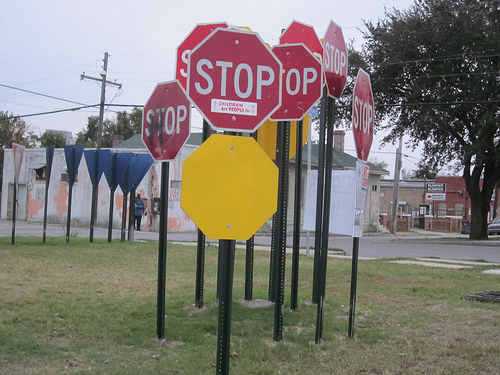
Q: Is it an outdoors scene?
A: Yes, it is outdoors.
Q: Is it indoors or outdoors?
A: It is outdoors.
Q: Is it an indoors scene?
A: No, it is outdoors.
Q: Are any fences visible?
A: No, there are no fences.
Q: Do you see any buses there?
A: No, there are no buses.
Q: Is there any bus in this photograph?
A: No, there are no buses.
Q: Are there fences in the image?
A: No, there are no fences.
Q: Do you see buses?
A: No, there are no buses.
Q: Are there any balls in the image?
A: No, there are no balls.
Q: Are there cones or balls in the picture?
A: No, there are no balls or cones.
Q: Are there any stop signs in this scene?
A: Yes, there is a stop sign.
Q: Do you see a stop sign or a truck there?
A: Yes, there is a stop sign.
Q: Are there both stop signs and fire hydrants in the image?
A: No, there is a stop sign but no fire hydrants.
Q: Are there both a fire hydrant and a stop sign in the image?
A: No, there is a stop sign but no fire hydrants.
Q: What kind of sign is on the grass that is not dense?
A: The sign is a stop sign.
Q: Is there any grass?
A: Yes, there is grass.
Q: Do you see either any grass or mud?
A: Yes, there is grass.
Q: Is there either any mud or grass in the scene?
A: Yes, there is grass.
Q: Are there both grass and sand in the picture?
A: No, there is grass but no sand.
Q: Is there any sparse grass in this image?
A: Yes, there is sparse grass.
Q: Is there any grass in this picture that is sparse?
A: Yes, there is sparse grass.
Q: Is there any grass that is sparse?
A: Yes, there is grass that is sparse.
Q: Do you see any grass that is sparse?
A: Yes, there is grass that is sparse.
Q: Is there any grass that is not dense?
A: Yes, there is sparse grass.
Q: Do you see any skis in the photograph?
A: No, there are no skis.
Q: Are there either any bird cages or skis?
A: No, there are no skis or bird cages.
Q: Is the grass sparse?
A: Yes, the grass is sparse.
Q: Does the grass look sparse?
A: Yes, the grass is sparse.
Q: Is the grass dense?
A: No, the grass is sparse.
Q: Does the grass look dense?
A: No, the grass is sparse.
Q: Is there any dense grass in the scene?
A: No, there is grass but it is sparse.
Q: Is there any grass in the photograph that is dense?
A: No, there is grass but it is sparse.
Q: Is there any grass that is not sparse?
A: No, there is grass but it is sparse.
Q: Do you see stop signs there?
A: Yes, there is a stop sign.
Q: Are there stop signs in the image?
A: Yes, there is a stop sign.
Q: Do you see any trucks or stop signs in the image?
A: Yes, there is a stop sign.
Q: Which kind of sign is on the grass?
A: The sign is a stop sign.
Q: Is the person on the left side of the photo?
A: Yes, the person is on the left of the image.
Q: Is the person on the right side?
A: No, the person is on the left of the image.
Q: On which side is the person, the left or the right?
A: The person is on the left of the image.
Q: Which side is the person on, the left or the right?
A: The person is on the left of the image.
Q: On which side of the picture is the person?
A: The person is on the left of the image.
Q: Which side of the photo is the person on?
A: The person is on the left of the image.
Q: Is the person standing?
A: Yes, the person is standing.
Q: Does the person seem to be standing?
A: Yes, the person is standing.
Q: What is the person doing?
A: The person is standing.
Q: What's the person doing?
A: The person is standing.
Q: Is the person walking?
A: No, the person is standing.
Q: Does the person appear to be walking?
A: No, the person is standing.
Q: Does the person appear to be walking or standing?
A: The person is standing.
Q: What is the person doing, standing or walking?
A: The person is standing.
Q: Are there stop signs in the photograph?
A: Yes, there is a stop sign.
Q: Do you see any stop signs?
A: Yes, there is a stop sign.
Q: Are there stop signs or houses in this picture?
A: Yes, there is a stop sign.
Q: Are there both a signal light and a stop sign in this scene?
A: No, there is a stop sign but no traffic lights.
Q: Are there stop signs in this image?
A: Yes, there is a stop sign.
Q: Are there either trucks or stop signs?
A: Yes, there is a stop sign.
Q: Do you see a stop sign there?
A: Yes, there is a stop sign.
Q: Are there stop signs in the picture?
A: Yes, there is a stop sign.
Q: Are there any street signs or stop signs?
A: Yes, there is a stop sign.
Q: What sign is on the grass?
A: The sign is a stop sign.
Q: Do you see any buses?
A: No, there are no buses.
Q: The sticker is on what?
A: The sticker is on the stop sign.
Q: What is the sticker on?
A: The sticker is on the stop sign.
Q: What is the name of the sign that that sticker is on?
A: The sign is a stop sign.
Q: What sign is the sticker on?
A: The sticker is on the stop sign.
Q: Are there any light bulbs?
A: No, there are no light bulbs.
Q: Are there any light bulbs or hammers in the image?
A: No, there are no light bulbs or hammers.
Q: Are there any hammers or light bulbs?
A: No, there are no light bulbs or hammers.